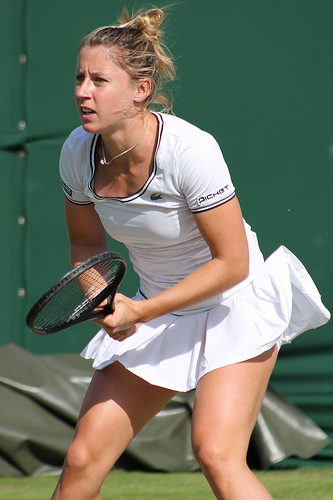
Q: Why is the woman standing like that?
A: She is waiting for the ball.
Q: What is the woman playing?
A: Tennis.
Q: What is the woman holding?
A: A racket.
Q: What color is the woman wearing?
A: White.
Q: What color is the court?
A: Green.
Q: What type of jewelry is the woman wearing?
A: A necklace.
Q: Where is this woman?
A: On a tennis court.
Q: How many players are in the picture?
A: One.